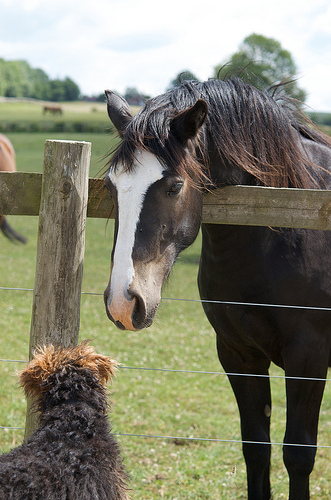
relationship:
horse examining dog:
[92, 70, 331, 498] [1, 341, 136, 498]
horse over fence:
[92, 70, 331, 498] [1, 139, 330, 447]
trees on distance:
[1, 58, 84, 103] [1, 59, 329, 98]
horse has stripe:
[92, 70, 331, 498] [107, 145, 167, 300]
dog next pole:
[1, 341, 136, 498] [20, 136, 93, 449]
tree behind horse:
[208, 22, 312, 106] [92, 70, 331, 498]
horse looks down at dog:
[65, 59, 329, 368] [1, 341, 136, 498]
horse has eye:
[92, 70, 331, 498] [150, 168, 219, 222]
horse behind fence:
[92, 70, 331, 498] [1, 138, 329, 492]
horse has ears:
[92, 70, 331, 498] [101, 83, 213, 142]